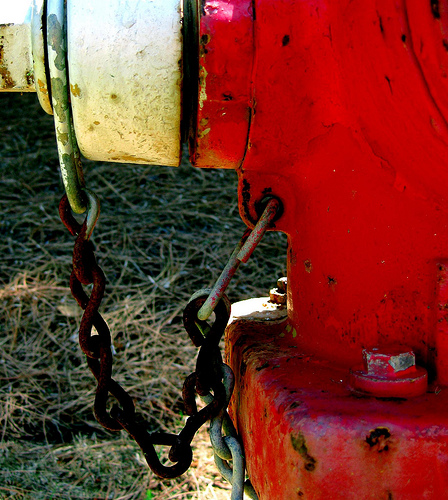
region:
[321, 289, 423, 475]
the hydrant is red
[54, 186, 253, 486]
a thick chain holds the cap on the hydrant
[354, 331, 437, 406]
the bolts holding it down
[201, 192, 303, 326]
the "S" hook that holds the chain in place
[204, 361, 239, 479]
this part of the chain is not rusted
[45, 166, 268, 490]
Chain on the hydrant.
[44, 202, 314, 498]
Rusty chain on the hydrant.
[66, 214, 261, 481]
Rusted chain on the red hydrant.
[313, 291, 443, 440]
Bolt on the hydrant.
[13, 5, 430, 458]
Red hydrant on the ground.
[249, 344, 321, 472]
Rust on the hydrant.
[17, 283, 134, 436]
Dry grass on the ground.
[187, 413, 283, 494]
Part of the chain.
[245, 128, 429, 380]
a bright red hydrant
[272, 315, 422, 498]
the hydrant is rusted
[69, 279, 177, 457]
a badly rusted chain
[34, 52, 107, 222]
a rusted spotted chain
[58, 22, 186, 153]
white cap of hydrant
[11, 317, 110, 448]
grass is low and dead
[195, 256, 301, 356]
bright white reflection spot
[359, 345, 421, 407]
a large nut on hydrant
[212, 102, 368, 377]
red paint is chipped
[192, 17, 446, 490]
red hydrant in part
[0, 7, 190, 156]
partial white arm of hydrant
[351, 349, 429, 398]
red nut on hydrant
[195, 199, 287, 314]
metal hook flecked with red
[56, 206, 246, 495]
chain hanging from hydrant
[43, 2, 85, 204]
metal ring on hydrant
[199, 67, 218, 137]
chipped paint on hydrant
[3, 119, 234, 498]
grass brown and dead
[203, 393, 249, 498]
metal chain hanging on hydrant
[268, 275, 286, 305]
bolt on hydrant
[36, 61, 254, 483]
chain on a fire hydrant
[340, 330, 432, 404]
red cap on a fire hydrant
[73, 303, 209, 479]
Old rusty chain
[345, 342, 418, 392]
red large screw on top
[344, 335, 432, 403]
bolt with red paint on it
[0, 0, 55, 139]
bolt with white paint on it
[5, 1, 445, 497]
red fire hydrant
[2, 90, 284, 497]
dead grass that is brown in color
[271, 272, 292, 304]
A rusty red bolt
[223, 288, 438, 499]
Base of the fire hydrant that is bolted down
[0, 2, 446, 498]
A chain connected to a hydrant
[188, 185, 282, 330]
A hook with red paint on it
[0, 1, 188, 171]
The the valve that lets the water out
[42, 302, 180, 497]
brown grass on the ground